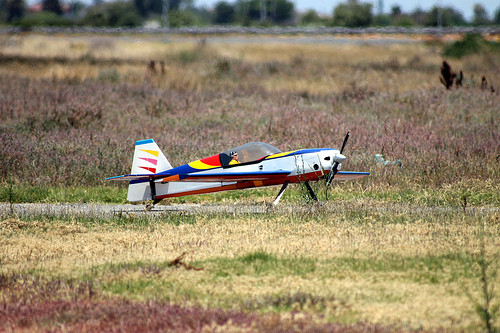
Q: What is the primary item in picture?
A: Airplane.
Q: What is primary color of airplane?
A: White.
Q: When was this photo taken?
A: Daytime.